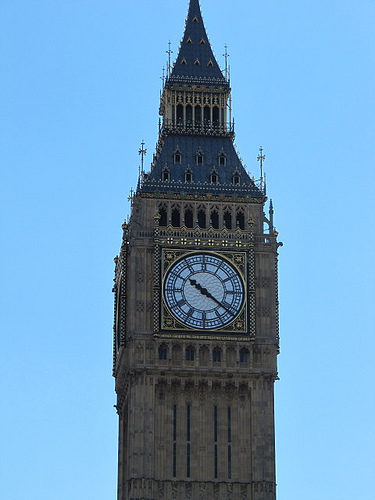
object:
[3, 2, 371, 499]
scene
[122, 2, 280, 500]
tower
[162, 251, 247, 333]
clock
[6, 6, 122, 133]
sky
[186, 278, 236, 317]
hands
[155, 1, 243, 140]
steeple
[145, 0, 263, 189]
steeple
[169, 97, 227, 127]
decorative arches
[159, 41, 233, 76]
crosses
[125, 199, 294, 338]
tower-top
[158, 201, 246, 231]
windows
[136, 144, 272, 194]
crosses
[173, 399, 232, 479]
vertical openings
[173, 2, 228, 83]
top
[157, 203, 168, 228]
window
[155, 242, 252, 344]
frame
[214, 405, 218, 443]
slit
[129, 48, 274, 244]
ornamentation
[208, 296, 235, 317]
minute hand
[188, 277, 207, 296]
hour hand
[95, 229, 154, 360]
corners